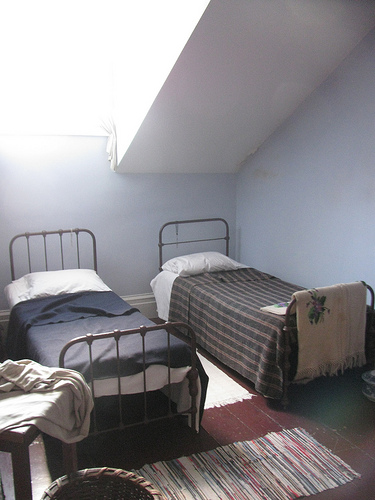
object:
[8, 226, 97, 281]
frame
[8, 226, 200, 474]
bed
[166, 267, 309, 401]
bed spread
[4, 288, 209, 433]
bed spread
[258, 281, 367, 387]
towel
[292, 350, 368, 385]
end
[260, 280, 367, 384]
blanket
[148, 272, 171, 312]
sheets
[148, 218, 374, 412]
bed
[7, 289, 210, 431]
blanket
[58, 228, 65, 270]
iron rod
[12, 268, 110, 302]
pillow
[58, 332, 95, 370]
frame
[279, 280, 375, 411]
frame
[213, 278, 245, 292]
part bed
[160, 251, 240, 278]
pillow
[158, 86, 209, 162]
top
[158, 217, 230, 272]
frame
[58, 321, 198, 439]
footboard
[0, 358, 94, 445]
blanket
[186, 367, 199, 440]
iron stand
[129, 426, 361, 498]
mat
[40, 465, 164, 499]
basket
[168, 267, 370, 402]
blanket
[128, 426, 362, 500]
carpet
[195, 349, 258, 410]
rug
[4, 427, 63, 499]
legs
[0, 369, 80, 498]
desk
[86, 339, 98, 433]
iron rod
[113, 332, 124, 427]
iron rod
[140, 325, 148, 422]
iron rod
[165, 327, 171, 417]
iron rod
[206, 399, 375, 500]
floor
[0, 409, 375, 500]
ground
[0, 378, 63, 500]
table